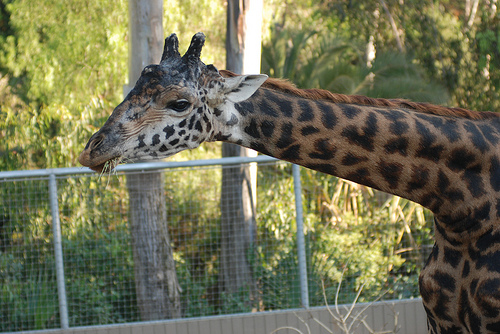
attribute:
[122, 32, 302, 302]
tree — trunk, brown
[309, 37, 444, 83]
foliage — dense, green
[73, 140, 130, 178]
mouth — open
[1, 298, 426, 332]
fence base — concrete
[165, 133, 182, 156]
brown spot — dark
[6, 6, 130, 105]
leaves — green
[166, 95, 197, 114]
eye — black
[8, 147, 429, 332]
fence — tall, metal, wire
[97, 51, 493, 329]
giraffe — brown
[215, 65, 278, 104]
ear — little, white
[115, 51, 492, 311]
giraffe — brown, spotted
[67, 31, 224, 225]
trunk — tall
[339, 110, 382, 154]
spot — brown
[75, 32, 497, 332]
giraffe — brown, eating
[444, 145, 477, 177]
brown spot —  brown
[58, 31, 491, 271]
giraffe — spotted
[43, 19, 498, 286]
giraffe — brown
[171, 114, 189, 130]
spt — brown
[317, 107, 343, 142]
spot —  brown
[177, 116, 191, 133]
spot — dark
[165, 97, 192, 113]
eye — shiny, black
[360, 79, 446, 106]
palm frond — green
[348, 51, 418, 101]
palm frond — green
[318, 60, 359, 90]
palm frond — green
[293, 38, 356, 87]
palm frond — green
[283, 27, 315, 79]
palm frond — green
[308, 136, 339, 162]
spot — brown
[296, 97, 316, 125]
spot — brown